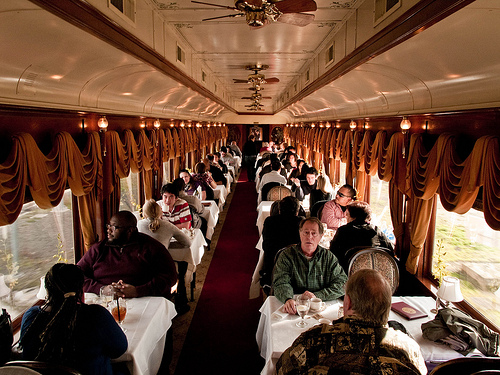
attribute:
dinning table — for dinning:
[7, 286, 175, 371]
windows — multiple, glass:
[436, 210, 498, 297]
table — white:
[263, 308, 315, 348]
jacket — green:
[99, 248, 151, 276]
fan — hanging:
[205, 0, 320, 34]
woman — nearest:
[15, 258, 130, 371]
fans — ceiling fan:
[184, 0, 321, 115]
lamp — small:
[431, 273, 466, 316]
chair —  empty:
[333, 243, 425, 295]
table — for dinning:
[138, 312, 147, 317]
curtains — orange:
[280, 113, 498, 339]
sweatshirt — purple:
[70, 234, 180, 296]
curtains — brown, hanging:
[284, 125, 499, 274]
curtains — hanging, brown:
[0, 127, 227, 252]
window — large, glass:
[2, 185, 76, 331]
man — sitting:
[267, 216, 350, 310]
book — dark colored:
[393, 295, 429, 326]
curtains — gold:
[2, 122, 228, 222]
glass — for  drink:
[108, 290, 127, 334]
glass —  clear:
[290, 290, 310, 330]